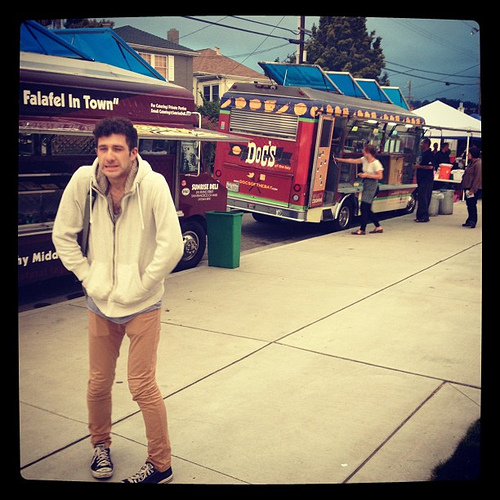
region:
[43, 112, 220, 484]
A man on the street with his hands in coat pockets.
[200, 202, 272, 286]
A green trash can sitting on the sidewalk.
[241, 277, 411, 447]
A grey sidewalk.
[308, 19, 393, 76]
A large green tree.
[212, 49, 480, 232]
Food vendors set up along a street serving food.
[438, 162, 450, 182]
Orange cooler sitting on top of table.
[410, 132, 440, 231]
Man dressed in black standing next to food truck.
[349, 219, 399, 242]
A pair of brown flip flops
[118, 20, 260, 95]
Two houses in the background.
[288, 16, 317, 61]
A brown telephone pole.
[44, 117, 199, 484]
man in white hooded sweatshirt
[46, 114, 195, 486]
man with hands in pockets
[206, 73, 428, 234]
food truck parked on the road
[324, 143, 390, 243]
woman wearing black pants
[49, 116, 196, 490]
man wearing dark blue sneakers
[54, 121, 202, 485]
man wearing tan pants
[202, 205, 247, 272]
green plastic garbage bin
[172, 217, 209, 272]
rubber truck tire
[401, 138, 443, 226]
man wearing black shirt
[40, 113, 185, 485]
man with dark colored hair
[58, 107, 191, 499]
man wearing white sweatshirt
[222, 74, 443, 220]
red taco truck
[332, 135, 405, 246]
woman wearing black pants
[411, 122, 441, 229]
man wearing black shirt and pants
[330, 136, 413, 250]
woman wearing white shirt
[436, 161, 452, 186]
orange bucket holding water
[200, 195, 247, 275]
green trash can next to truck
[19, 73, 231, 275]
purple food truck serving Falafel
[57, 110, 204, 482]
man wearing black and white shoes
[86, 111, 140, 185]
the head of a man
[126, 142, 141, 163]
the ear of a man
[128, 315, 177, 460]
the leg of a man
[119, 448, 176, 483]
a black tennis shoe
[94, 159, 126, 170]
the mouth of a man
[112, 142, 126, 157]
the eye of a man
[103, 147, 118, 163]
the nose of a man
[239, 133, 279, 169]
white writing on the truck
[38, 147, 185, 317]
a white hoodie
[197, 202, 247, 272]
a green trash can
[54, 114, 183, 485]
man standing in a funny pose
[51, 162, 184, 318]
light colored long sleeved hoodie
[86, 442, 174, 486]
man's black shoes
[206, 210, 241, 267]
tall, green trash can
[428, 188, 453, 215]
two metal trash cans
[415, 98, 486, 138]
white colored tent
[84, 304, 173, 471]
man's brown pair of pants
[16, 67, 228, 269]
the falafel food truck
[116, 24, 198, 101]
top of gray house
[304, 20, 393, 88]
a big green tree